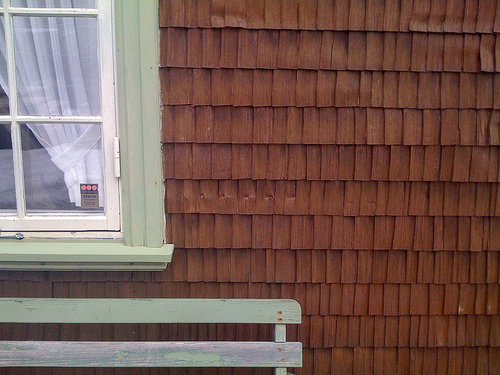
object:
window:
[12, 113, 112, 220]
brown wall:
[0, 0, 499, 375]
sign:
[78, 183, 100, 210]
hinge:
[111, 137, 129, 182]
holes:
[276, 315, 284, 325]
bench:
[0, 292, 305, 375]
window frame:
[1, 1, 177, 275]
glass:
[18, 121, 110, 217]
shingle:
[271, 248, 297, 284]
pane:
[9, 116, 105, 218]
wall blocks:
[172, 141, 194, 180]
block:
[164, 65, 199, 108]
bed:
[0, 142, 105, 210]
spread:
[0, 148, 77, 209]